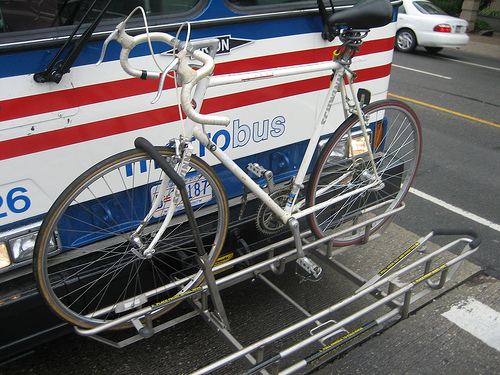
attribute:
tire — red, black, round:
[305, 93, 425, 248]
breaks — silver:
[95, 24, 186, 115]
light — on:
[347, 127, 375, 158]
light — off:
[6, 221, 63, 264]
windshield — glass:
[2, 2, 305, 40]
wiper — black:
[35, 7, 105, 90]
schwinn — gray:
[319, 72, 345, 126]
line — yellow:
[423, 93, 498, 126]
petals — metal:
[282, 234, 331, 290]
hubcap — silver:
[398, 32, 412, 50]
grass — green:
[473, 18, 490, 32]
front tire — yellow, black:
[29, 141, 236, 337]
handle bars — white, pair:
[90, 19, 239, 127]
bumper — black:
[3, 283, 51, 357]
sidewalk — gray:
[471, 35, 493, 57]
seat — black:
[320, 1, 399, 33]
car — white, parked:
[396, 1, 479, 59]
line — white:
[393, 60, 463, 89]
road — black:
[435, 130, 492, 181]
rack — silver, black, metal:
[90, 203, 479, 373]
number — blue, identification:
[1, 185, 40, 215]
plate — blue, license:
[147, 177, 213, 219]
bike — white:
[31, 5, 440, 304]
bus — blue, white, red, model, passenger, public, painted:
[3, 2, 413, 280]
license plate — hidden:
[131, 176, 205, 207]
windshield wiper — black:
[37, 12, 106, 88]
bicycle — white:
[39, 54, 415, 290]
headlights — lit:
[2, 231, 53, 265]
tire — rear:
[394, 28, 417, 56]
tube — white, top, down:
[220, 144, 292, 203]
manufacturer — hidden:
[159, 31, 244, 72]